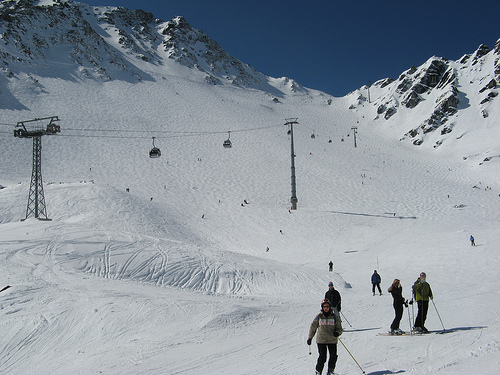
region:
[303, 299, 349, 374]
a person on the snow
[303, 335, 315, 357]
a ski pole in the person's hand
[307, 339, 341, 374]
a pair of black pants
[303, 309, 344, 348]
a gray sweat shirt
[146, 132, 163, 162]
a tram car on the wire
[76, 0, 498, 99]
a clear blue sky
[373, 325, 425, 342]
a pair of skis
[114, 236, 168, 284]
ski tracks on the snow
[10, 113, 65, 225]
a ski lift pole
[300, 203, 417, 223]
a shadow on the ground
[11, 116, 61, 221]
the ski lift tower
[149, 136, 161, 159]
ski lift chair gets skiers to the top of the ski slope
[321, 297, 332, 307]
a skiers helmet used for safety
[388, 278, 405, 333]
a skier is wearing a black ski jacket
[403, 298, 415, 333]
a skiers ski poles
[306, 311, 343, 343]
the skier is wearing a brown ski jacket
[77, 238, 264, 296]
ski tracks from skiers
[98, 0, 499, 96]
cloudless dark blue skies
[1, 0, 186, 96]
the top of the mountain peaks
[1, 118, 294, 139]
the ski lift cables that the chairs connect to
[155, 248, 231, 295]
lot of ski tracks in the snow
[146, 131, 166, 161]
a ski lift carrying some skiers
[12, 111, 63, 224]
ski tower that runs cable for the lifts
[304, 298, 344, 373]
skier with goggles and hat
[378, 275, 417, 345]
female skier dressed in black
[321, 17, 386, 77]
sky above the ski slopes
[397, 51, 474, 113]
rocky side of a mountain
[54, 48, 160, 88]
shadow cast by mountain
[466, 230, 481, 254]
skier in blue in the background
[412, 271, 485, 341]
skier and his shadow in snow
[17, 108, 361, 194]
ski lift up a snowy mountain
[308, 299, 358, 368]
skier in a tan jacket with poles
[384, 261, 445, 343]
two people skiing together with poles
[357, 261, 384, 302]
a lone skier without poles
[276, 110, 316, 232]
a metal tower for the ski lift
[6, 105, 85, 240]
a metal tower for a ski lift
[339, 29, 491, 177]
skiing mountains covered in snow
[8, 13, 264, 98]
rocky mountains covered in snow too steep to ski down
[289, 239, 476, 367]
multiple skiers downhill skiing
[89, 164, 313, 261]
skiers in the distance downhill skiing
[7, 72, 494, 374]
a snowy ski slope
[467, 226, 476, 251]
a skier in a blue coat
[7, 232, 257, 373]
the snow is white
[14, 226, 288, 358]
the snow is cold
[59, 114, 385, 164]
the ski lift is running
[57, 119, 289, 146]
the ski lift has cables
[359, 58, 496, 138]
the ski slope is mountainous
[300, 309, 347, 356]
the skier has a tan coat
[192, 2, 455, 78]
the ski is blue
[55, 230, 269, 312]
ski tracks in the snow